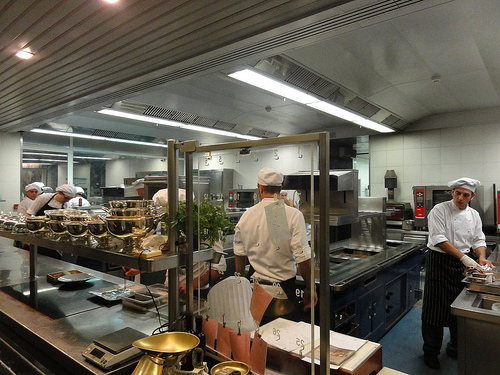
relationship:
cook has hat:
[422, 177, 496, 370] [447, 178, 479, 192]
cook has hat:
[234, 169, 318, 320] [256, 171, 286, 190]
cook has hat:
[16, 183, 38, 219] [24, 183, 38, 190]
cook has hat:
[27, 184, 76, 216] [56, 184, 78, 198]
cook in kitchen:
[16, 183, 38, 219] [3, 3, 496, 372]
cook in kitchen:
[27, 184, 76, 216] [3, 3, 496, 372]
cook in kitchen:
[234, 169, 318, 320] [3, 3, 496, 372]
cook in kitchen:
[422, 177, 496, 370] [3, 3, 496, 372]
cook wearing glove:
[422, 177, 496, 370] [461, 257, 484, 274]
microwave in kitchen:
[411, 183, 485, 226] [3, 3, 496, 372]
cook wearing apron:
[422, 177, 496, 370] [420, 250, 475, 326]